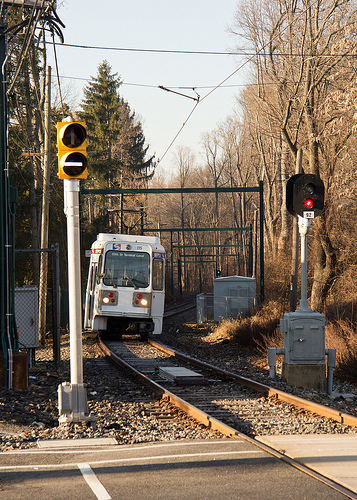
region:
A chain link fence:
[12, 242, 62, 375]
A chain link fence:
[196, 290, 257, 326]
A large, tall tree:
[70, 62, 156, 188]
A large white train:
[81, 233, 167, 341]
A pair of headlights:
[101, 291, 147, 306]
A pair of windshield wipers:
[103, 260, 146, 289]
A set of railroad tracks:
[94, 297, 355, 499]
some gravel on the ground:
[0, 300, 353, 448]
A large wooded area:
[8, 0, 355, 319]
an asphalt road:
[0, 437, 343, 498]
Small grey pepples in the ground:
[137, 420, 153, 435]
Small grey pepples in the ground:
[164, 422, 192, 435]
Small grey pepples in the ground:
[89, 423, 128, 445]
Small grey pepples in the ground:
[14, 426, 75, 453]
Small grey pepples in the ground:
[20, 391, 59, 427]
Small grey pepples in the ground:
[242, 401, 298, 461]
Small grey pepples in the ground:
[242, 350, 275, 380]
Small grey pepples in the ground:
[188, 340, 235, 362]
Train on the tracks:
[86, 225, 214, 401]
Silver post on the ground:
[55, 181, 100, 443]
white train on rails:
[64, 221, 199, 347]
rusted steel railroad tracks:
[124, 386, 254, 452]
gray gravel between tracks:
[119, 406, 167, 446]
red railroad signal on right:
[272, 169, 323, 224]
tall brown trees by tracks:
[194, 107, 316, 242]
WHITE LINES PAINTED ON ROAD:
[94, 451, 147, 496]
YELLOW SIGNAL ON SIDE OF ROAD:
[55, 116, 93, 190]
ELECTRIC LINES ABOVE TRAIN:
[110, 34, 299, 169]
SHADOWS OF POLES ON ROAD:
[16, 449, 304, 480]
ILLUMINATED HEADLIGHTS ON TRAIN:
[95, 289, 172, 310]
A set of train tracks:
[92, 298, 356, 499]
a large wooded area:
[1, 4, 355, 339]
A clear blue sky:
[6, 2, 355, 186]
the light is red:
[281, 161, 325, 222]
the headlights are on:
[83, 283, 161, 316]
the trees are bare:
[163, 122, 280, 268]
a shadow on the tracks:
[116, 332, 283, 420]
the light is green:
[206, 263, 223, 275]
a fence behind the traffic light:
[0, 240, 63, 360]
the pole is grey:
[48, 165, 91, 403]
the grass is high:
[253, 297, 350, 400]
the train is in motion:
[42, 205, 188, 355]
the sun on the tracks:
[243, 388, 347, 459]